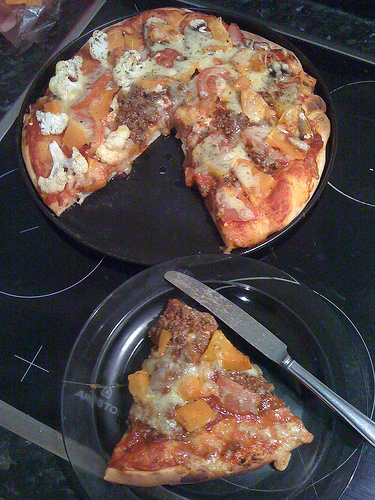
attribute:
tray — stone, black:
[17, 7, 337, 270]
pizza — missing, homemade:
[19, 7, 330, 248]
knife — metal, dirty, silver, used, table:
[163, 268, 374, 448]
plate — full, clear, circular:
[59, 253, 374, 496]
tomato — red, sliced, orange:
[198, 66, 228, 100]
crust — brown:
[103, 426, 312, 491]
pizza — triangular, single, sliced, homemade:
[103, 299, 312, 481]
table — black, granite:
[2, 3, 366, 499]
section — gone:
[61, 129, 224, 252]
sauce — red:
[28, 102, 90, 200]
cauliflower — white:
[35, 109, 70, 135]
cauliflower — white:
[40, 141, 88, 192]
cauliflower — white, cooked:
[98, 124, 134, 164]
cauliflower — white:
[55, 55, 86, 81]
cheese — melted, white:
[127, 345, 231, 437]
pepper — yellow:
[208, 16, 231, 46]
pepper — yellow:
[149, 22, 178, 48]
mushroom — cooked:
[191, 19, 207, 37]